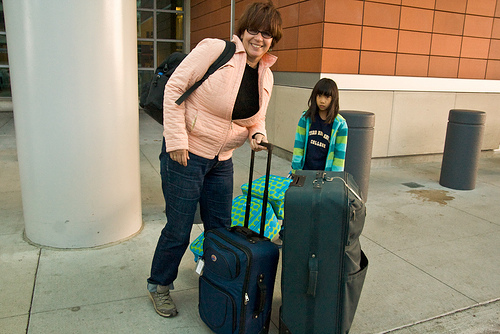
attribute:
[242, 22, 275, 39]
glasses — black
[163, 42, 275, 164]
jacket — peach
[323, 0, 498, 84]
wall — black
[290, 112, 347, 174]
jacket — turquoise, green, striped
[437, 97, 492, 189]
trashcan — grey, metal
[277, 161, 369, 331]
suitcase — green 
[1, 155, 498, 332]
sidewalk — concrete 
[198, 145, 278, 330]
suitcase — navy blue, black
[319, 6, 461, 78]
wall — black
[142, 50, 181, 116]
backpack — black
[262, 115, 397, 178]
sweater — green, blue striped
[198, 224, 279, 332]
suitcase — blue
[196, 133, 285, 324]
carry on — pieces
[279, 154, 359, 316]
carry on — pieces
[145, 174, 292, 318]
jeans — blue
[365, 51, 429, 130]
wall — black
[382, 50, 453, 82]
wall — black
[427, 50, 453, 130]
wall — black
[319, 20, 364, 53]
block — brown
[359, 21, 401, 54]
block — brown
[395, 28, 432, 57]
block — brown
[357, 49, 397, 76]
block — brown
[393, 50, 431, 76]
block — brown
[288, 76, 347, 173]
girl — caught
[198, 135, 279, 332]
luggage — green, blue polka dot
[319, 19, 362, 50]
brick — orange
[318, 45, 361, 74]
brick — orange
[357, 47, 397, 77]
brick — orange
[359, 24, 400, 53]
brick — orange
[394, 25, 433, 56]
brick — orange